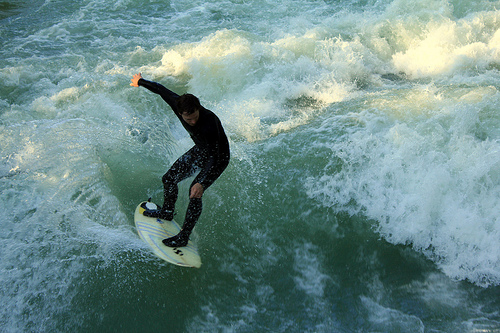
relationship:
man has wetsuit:
[126, 72, 232, 250] [138, 79, 232, 248]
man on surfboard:
[126, 72, 232, 250] [132, 197, 204, 270]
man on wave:
[126, 72, 232, 250] [52, 5, 498, 135]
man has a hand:
[126, 72, 232, 250] [126, 71, 144, 90]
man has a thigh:
[126, 72, 232, 250] [162, 146, 194, 179]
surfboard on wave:
[132, 197, 204, 270] [52, 5, 498, 135]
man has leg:
[126, 72, 232, 250] [161, 147, 194, 214]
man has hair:
[126, 72, 232, 250] [177, 92, 200, 117]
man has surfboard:
[126, 72, 232, 250] [132, 197, 204, 270]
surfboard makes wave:
[132, 197, 204, 270] [52, 5, 498, 135]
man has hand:
[126, 72, 232, 250] [126, 71, 144, 90]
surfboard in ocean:
[132, 197, 204, 270] [2, 2, 499, 332]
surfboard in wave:
[132, 197, 204, 270] [52, 5, 498, 135]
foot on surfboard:
[163, 229, 191, 249] [132, 197, 204, 270]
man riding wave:
[126, 72, 232, 250] [52, 5, 498, 135]